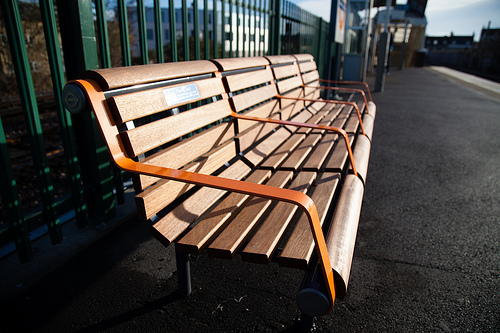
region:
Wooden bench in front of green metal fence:
[57, 48, 382, 321]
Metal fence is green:
[0, 0, 333, 269]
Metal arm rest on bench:
[70, 81, 338, 311]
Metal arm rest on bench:
[232, 108, 359, 176]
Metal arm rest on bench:
[277, 92, 364, 134]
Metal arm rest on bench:
[307, 82, 371, 112]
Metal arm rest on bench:
[318, 77, 373, 101]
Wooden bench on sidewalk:
[62, 50, 380, 332]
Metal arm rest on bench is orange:
[78, 81, 339, 306]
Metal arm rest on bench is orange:
[213, 68, 360, 175]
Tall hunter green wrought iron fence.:
[7, 5, 267, 51]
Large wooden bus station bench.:
[56, 55, 379, 311]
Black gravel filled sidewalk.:
[394, 90, 494, 330]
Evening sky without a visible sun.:
[439, 0, 498, 24]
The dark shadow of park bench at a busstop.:
[100, 250, 172, 329]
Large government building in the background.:
[132, 11, 287, 53]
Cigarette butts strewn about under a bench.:
[143, 257, 324, 329]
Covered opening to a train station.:
[339, 3, 435, 78]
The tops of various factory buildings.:
[429, 20, 498, 45]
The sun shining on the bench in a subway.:
[148, 93, 365, 226]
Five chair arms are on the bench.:
[125, 77, 373, 308]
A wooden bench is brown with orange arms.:
[62, 54, 376, 324]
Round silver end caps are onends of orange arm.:
[60, 80, 332, 317]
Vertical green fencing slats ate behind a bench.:
[5, 2, 335, 256]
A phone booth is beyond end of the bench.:
[337, 0, 371, 88]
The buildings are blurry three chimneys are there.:
[426, 20, 499, 72]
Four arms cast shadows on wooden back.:
[178, 76, 325, 196]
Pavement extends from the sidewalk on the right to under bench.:
[0, 60, 499, 331]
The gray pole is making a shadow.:
[80, 244, 193, 330]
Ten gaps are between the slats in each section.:
[87, 55, 369, 280]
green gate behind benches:
[3, 8, 348, 215]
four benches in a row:
[107, 35, 379, 272]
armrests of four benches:
[174, 62, 366, 257]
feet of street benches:
[177, 258, 314, 323]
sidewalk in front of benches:
[364, 43, 497, 327]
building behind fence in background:
[120, 4, 265, 64]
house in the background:
[426, 28, 473, 64]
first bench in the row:
[86, 70, 367, 285]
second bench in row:
[222, 53, 377, 175]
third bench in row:
[272, 48, 382, 128]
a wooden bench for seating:
[80, 18, 381, 278]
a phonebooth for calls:
[338, 1, 375, 81]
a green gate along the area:
[5, 3, 342, 191]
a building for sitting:
[378, 5, 451, 100]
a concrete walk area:
[370, 59, 498, 230]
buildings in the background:
[428, 19, 495, 76]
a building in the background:
[103, 5, 278, 55]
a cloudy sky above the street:
[426, 1, 496, 43]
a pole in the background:
[377, 18, 396, 109]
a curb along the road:
[435, 62, 497, 107]